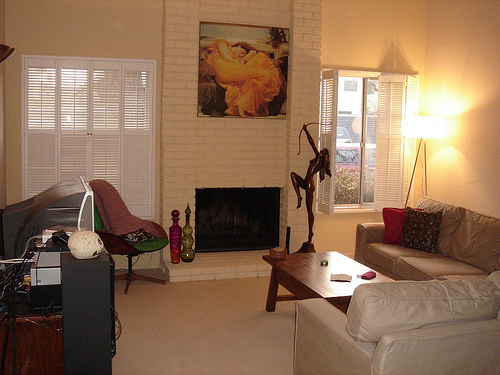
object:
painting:
[195, 21, 287, 119]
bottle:
[167, 206, 182, 267]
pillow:
[398, 207, 438, 254]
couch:
[286, 195, 500, 375]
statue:
[287, 121, 333, 252]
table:
[260, 248, 399, 313]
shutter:
[314, 70, 340, 216]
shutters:
[89, 56, 161, 219]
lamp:
[401, 112, 443, 211]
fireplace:
[193, 183, 280, 257]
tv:
[0, 174, 97, 262]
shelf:
[1, 308, 71, 375]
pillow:
[381, 207, 414, 245]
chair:
[79, 177, 173, 294]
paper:
[327, 272, 351, 284]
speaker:
[58, 250, 113, 375]